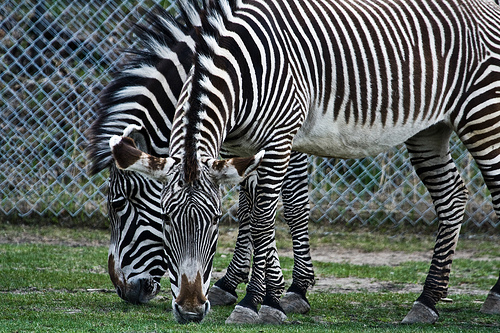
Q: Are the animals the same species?
A: Yes, all the animals are zebras.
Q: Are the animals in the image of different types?
A: No, all the animals are zebras.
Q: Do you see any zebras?
A: Yes, there is a zebra.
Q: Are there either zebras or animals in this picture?
A: Yes, there is a zebra.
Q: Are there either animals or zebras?
A: Yes, there is a zebra.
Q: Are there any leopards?
A: No, there are no leopards.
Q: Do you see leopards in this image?
A: No, there are no leopards.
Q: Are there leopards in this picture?
A: No, there are no leopards.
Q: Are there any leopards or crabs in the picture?
A: No, there are no leopards or crabs.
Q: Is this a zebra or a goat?
A: This is a zebra.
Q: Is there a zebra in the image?
A: Yes, there is a zebra.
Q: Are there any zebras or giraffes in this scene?
A: Yes, there is a zebra.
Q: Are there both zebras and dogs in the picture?
A: No, there is a zebra but no dogs.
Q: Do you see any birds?
A: No, there are no birds.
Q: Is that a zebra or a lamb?
A: That is a zebra.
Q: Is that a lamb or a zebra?
A: That is a zebra.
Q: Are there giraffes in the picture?
A: No, there are no giraffes.